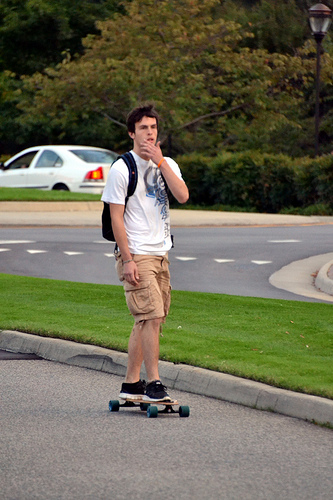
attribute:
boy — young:
[107, 106, 189, 402]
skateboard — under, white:
[106, 399, 190, 420]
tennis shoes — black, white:
[142, 380, 169, 404]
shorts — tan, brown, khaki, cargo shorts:
[116, 249, 171, 324]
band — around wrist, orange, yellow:
[156, 155, 168, 167]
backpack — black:
[100, 151, 138, 241]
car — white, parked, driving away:
[1, 143, 119, 195]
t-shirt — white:
[101, 158, 184, 255]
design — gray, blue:
[144, 165, 168, 235]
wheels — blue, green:
[148, 407, 158, 416]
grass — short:
[1, 271, 333, 400]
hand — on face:
[140, 142, 165, 165]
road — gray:
[2, 349, 331, 500]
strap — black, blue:
[121, 151, 137, 202]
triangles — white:
[251, 256, 271, 268]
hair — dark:
[125, 106, 155, 133]